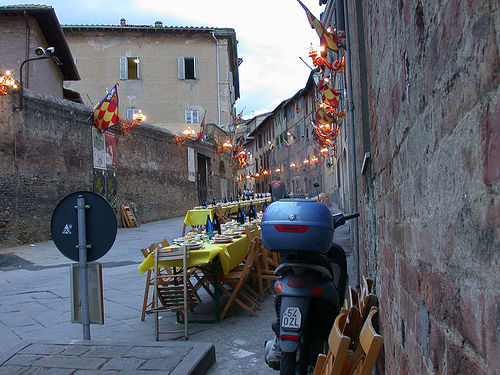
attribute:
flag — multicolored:
[313, 77, 347, 111]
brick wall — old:
[347, 30, 498, 371]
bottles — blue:
[211, 198, 259, 230]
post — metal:
[75, 197, 90, 342]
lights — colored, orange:
[228, 20, 345, 191]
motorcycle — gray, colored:
[253, 195, 372, 372]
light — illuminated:
[129, 54, 143, 68]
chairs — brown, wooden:
[135, 219, 280, 334]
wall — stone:
[0, 82, 238, 241]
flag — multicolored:
[195, 114, 205, 145]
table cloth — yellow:
[115, 187, 282, 299]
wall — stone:
[266, 50, 474, 343]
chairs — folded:
[315, 277, 390, 372]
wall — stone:
[238, 0, 498, 372]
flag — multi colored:
[75, 70, 133, 150]